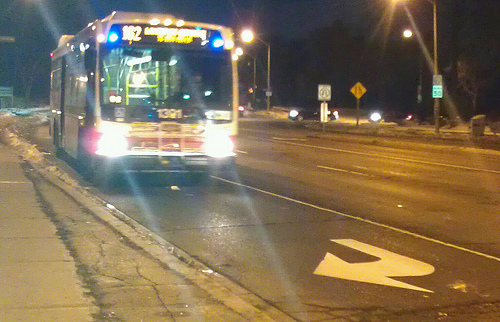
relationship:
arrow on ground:
[312, 235, 436, 296] [1, 105, 499, 321]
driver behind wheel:
[190, 71, 209, 90] [193, 89, 213, 97]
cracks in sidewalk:
[65, 212, 177, 320] [1, 141, 302, 322]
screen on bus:
[119, 23, 210, 47] [47, 8, 241, 183]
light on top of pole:
[240, 28, 255, 44] [256, 36, 275, 112]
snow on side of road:
[0, 105, 80, 186] [33, 120, 500, 322]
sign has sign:
[432, 84, 443, 100] [432, 84, 443, 100]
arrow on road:
[312, 235, 436, 296] [33, 120, 500, 322]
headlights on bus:
[95, 129, 236, 161] [47, 8, 241, 183]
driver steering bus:
[190, 71, 209, 90] [47, 8, 241, 183]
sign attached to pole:
[432, 84, 443, 100] [431, 2, 443, 134]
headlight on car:
[289, 108, 299, 119] [287, 105, 340, 124]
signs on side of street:
[431, 73, 445, 100] [33, 122, 499, 321]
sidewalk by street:
[1, 141, 302, 322] [33, 122, 499, 321]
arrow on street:
[312, 235, 436, 296] [33, 122, 499, 321]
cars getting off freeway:
[287, 104, 416, 126] [279, 114, 499, 136]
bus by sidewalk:
[47, 8, 241, 183] [1, 141, 302, 322]